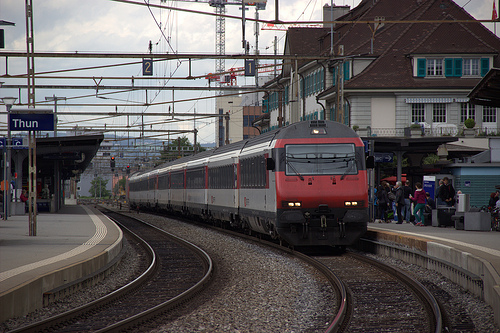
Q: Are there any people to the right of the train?
A: Yes, there are people to the right of the train.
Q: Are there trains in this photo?
A: Yes, there is a train.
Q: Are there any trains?
A: Yes, there is a train.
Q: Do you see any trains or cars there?
A: Yes, there is a train.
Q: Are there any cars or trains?
A: Yes, there is a train.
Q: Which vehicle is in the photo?
A: The vehicle is a train.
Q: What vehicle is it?
A: The vehicle is a train.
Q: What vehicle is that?
A: This is a train.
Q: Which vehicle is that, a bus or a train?
A: This is a train.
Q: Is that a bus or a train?
A: That is a train.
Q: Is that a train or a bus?
A: That is a train.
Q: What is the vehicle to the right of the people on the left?
A: The vehicle is a train.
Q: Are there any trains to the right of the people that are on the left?
A: Yes, there is a train to the right of the people.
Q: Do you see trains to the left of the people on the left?
A: No, the train is to the right of the people.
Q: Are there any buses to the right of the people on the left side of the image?
A: No, there is a train to the right of the people.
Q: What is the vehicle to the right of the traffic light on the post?
A: The vehicle is a train.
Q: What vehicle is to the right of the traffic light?
A: The vehicle is a train.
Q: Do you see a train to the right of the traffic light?
A: Yes, there is a train to the right of the traffic light.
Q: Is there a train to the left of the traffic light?
A: No, the train is to the right of the traffic light.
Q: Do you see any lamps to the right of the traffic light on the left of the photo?
A: No, there is a train to the right of the traffic signal.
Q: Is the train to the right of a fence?
A: No, the train is to the right of the traffic signal.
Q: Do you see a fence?
A: No, there are no fences.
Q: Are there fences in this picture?
A: No, there are no fences.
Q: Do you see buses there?
A: No, there are no buses.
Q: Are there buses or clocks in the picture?
A: No, there are no buses or clocks.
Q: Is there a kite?
A: No, there are no kites.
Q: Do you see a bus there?
A: No, there are no buses.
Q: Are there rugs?
A: No, there are no rugs.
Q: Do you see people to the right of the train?
A: Yes, there are people to the right of the train.